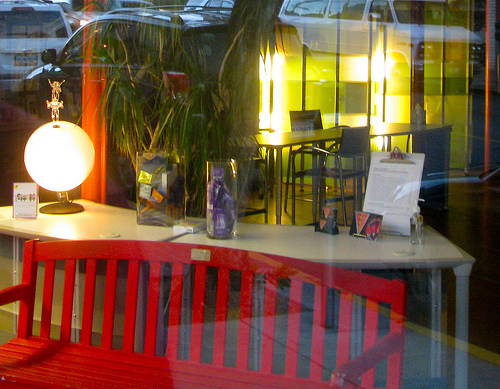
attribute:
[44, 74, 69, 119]
object — golden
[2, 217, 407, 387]
bench — wooden, red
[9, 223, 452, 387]
bench — red, wooden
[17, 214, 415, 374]
bench — wooden, red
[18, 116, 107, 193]
lamp — illuminated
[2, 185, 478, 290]
table top — white, curved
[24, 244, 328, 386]
bench — red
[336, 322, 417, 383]
wooden arm — red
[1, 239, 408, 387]
red bench — wooden, wood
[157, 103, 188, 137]
leaves — green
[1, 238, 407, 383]
bench — wood, red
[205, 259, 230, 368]
slat — red, wooden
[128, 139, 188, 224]
vase — filled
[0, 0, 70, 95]
car — reflection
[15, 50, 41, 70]
license plate — reflection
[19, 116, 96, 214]
light — round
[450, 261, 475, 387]
table leg — silver, white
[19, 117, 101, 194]
lamp — round, yellow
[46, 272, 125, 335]
slat — red, wooden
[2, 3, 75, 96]
van — white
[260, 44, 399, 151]
light — shining